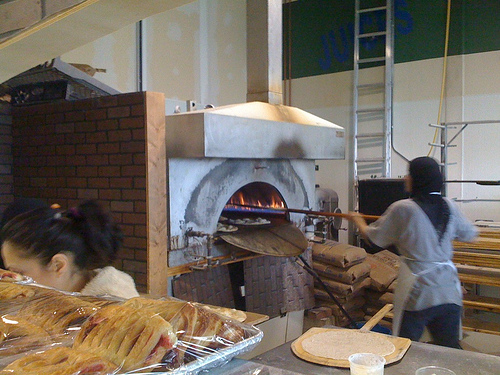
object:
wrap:
[4, 284, 266, 375]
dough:
[302, 327, 395, 360]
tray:
[289, 302, 412, 368]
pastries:
[0, 271, 262, 375]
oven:
[166, 101, 346, 317]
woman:
[351, 156, 480, 353]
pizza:
[217, 215, 272, 233]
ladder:
[351, 0, 394, 255]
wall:
[251, 1, 499, 242]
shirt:
[365, 199, 478, 312]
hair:
[3, 198, 126, 273]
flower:
[311, 236, 399, 324]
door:
[219, 220, 309, 258]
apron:
[392, 260, 464, 340]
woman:
[4, 199, 151, 304]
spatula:
[233, 201, 386, 221]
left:
[0, 131, 5, 372]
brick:
[170, 233, 319, 316]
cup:
[347, 352, 383, 374]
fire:
[223, 183, 285, 214]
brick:
[3, 91, 166, 293]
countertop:
[218, 325, 499, 375]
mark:
[267, 105, 310, 160]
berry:
[150, 333, 174, 355]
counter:
[276, 323, 500, 374]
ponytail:
[71, 199, 120, 270]